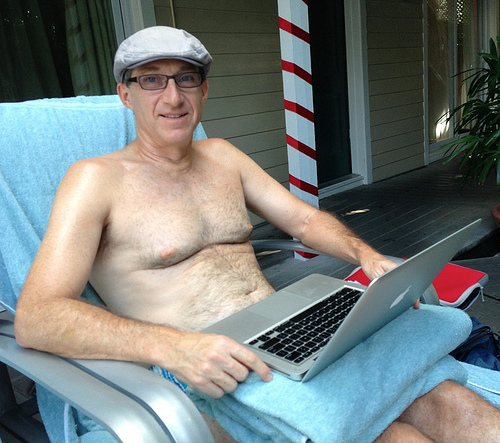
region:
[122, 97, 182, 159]
this is a head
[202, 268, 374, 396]
this is a laptop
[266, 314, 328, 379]
this is a macbook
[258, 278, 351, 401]
this is a computer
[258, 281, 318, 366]
the computer is silver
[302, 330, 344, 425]
the computer is made of metal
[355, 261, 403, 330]
this is the logo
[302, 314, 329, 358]
this is the keyboard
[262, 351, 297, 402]
the keyboard is black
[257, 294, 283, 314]
this is a trackpad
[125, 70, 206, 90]
glasses on man's face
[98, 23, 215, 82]
hat on man's head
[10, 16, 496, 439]
man sitting in lounge chair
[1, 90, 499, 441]
lounge chair on porch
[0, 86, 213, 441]
blue towel covering back of lounge chair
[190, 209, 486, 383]
laptop computer in man's lap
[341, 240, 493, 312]
red and gray laptop computer case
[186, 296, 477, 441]
folded blue blanket beneath laptop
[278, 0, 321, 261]
white beam with red stripes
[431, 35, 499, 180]
green plant on porch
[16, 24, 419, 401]
shirtless man looking at the camera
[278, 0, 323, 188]
white post with red stripes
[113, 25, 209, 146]
man wearing eyeglasses and a hat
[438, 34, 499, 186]
green leaves of an outdoor plant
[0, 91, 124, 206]
blue towel draped over the back of the man's chair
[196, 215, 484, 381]
laptop computer on the man's lap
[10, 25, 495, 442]
man with a laptop computer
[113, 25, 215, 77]
man's cap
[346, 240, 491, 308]
gray and red zippered case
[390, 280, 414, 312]
Apple logo on the man's computer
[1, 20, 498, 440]
content shirtless man relaxing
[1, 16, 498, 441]
man with no shirt sitting down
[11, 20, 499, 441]
happy man without a shirt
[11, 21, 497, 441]
shirtless man wearing a hat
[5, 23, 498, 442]
sitting man exposing his bare chest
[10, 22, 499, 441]
seated man with hair on his chest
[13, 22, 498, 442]
smiling man holding a laptop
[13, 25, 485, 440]
blue eyed man holding his apple laptop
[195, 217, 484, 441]
silver apple laptop on towels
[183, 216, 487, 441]
laptop on folded blue towels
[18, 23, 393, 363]
The man is shirtless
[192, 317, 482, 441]
There is a towel on his lap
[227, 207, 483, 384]
There is a laptop on the towel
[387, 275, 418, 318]
The laptop is made by Apple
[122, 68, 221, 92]
He is wearing glasses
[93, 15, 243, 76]
He is wearing a hat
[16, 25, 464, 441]
The man is sitting on the porch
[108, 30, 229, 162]
He is looking at the camera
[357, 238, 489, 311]
A red computer case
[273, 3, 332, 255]
Pole designed to look like a candy cane